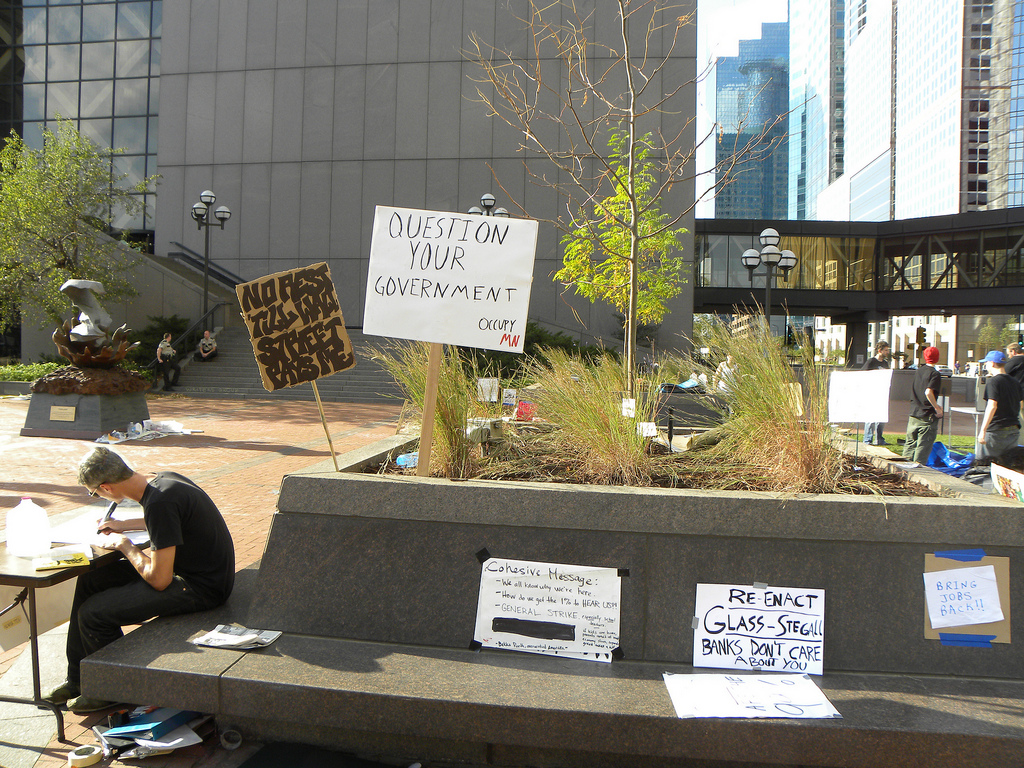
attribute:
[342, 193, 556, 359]
sign — white, handmade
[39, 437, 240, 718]
person — writing, sitting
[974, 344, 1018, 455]
person — standing up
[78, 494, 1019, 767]
bench — gray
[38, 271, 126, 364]
statue — silver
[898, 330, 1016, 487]
two people — standing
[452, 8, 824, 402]
tree — thin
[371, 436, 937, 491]
mulch — brown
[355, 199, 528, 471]
posterboard — white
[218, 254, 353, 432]
cardboard sign — brown, black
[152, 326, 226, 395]
two police officers — conversing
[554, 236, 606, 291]
leaves — bright green